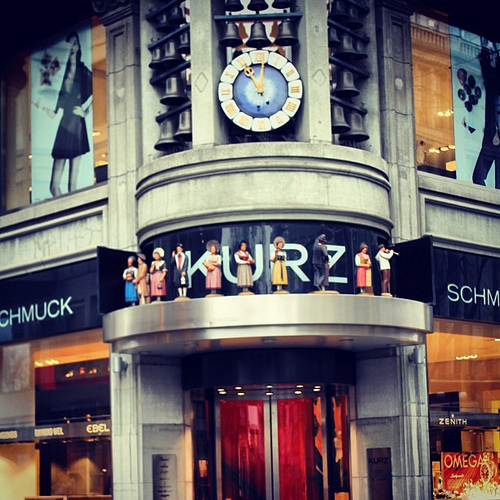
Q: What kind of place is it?
A: It is a store.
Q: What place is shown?
A: It is a store.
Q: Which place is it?
A: It is a store.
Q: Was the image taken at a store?
A: Yes, it was taken in a store.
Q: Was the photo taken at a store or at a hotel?
A: It was taken at a store.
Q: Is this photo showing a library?
A: No, the picture is showing a store.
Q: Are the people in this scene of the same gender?
A: Yes, all the people are female.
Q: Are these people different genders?
A: No, all the people are female.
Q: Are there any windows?
A: Yes, there is a window.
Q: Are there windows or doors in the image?
A: Yes, there is a window.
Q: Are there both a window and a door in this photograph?
A: Yes, there are both a window and a door.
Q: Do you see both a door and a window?
A: Yes, there are both a window and a door.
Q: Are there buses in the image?
A: No, there are no buses.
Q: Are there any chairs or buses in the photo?
A: No, there are no buses or chairs.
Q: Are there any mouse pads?
A: No, there are no mouse pads.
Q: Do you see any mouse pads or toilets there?
A: No, there are no mouse pads or toilets.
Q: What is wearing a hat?
A: The statue is wearing a hat.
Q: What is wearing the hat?
A: The statue is wearing a hat.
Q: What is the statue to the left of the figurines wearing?
A: The statue is wearing a hat.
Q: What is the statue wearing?
A: The statue is wearing a hat.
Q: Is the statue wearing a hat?
A: Yes, the statue is wearing a hat.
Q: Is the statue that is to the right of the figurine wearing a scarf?
A: No, the statue is wearing a hat.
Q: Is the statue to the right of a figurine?
A: Yes, the statue is to the right of a figurine.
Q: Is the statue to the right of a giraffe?
A: No, the statue is to the right of a figurine.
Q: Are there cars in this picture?
A: No, there are no cars.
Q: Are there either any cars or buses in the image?
A: No, there are no cars or buses.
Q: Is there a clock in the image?
A: Yes, there is a clock.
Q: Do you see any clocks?
A: Yes, there is a clock.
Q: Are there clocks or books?
A: Yes, there is a clock.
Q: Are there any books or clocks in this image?
A: Yes, there is a clock.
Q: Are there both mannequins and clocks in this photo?
A: No, there is a clock but no mannequins.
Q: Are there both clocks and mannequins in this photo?
A: No, there is a clock but no mannequins.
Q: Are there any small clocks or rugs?
A: Yes, there is a small clock.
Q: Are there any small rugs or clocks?
A: Yes, there is a small clock.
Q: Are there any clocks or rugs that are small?
A: Yes, the clock is small.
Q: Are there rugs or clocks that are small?
A: Yes, the clock is small.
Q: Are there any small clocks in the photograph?
A: Yes, there is a small clock.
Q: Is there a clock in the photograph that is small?
A: Yes, there is a clock that is small.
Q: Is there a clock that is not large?
A: Yes, there is a small clock.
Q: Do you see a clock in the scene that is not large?
A: Yes, there is a small clock.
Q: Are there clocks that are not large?
A: Yes, there is a small clock.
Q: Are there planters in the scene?
A: No, there are no planters.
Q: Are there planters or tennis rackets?
A: No, there are no planters or tennis rackets.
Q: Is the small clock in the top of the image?
A: Yes, the clock is in the top of the image.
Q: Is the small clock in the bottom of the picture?
A: No, the clock is in the top of the image.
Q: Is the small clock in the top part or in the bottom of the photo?
A: The clock is in the top of the image.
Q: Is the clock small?
A: Yes, the clock is small.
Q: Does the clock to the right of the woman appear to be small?
A: Yes, the clock is small.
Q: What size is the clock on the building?
A: The clock is small.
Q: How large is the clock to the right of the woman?
A: The clock is small.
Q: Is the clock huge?
A: No, the clock is small.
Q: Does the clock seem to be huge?
A: No, the clock is small.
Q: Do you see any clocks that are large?
A: No, there is a clock but it is small.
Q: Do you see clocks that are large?
A: No, there is a clock but it is small.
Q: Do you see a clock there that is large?
A: No, there is a clock but it is small.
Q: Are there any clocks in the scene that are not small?
A: No, there is a clock but it is small.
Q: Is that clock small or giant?
A: The clock is small.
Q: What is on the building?
A: The clock is on the building.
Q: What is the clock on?
A: The clock is on the building.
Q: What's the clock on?
A: The clock is on the building.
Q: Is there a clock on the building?
A: Yes, there is a clock on the building.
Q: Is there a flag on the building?
A: No, there is a clock on the building.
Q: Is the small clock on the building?
A: Yes, the clock is on the building.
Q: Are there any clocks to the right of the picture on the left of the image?
A: Yes, there is a clock to the right of the picture.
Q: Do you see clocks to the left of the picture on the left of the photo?
A: No, the clock is to the right of the picture.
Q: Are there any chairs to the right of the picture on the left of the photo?
A: No, there is a clock to the right of the picture.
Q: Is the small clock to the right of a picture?
A: Yes, the clock is to the right of a picture.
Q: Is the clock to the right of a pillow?
A: No, the clock is to the right of a picture.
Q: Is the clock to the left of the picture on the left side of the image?
A: No, the clock is to the right of the picture.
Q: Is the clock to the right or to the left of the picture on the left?
A: The clock is to the right of the picture.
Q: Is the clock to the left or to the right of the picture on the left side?
A: The clock is to the right of the picture.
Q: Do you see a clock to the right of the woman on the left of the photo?
A: Yes, there is a clock to the right of the woman.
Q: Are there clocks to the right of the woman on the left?
A: Yes, there is a clock to the right of the woman.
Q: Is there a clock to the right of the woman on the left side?
A: Yes, there is a clock to the right of the woman.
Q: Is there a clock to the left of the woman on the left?
A: No, the clock is to the right of the woman.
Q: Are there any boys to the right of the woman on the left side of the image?
A: No, there is a clock to the right of the woman.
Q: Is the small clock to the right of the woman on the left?
A: Yes, the clock is to the right of the woman.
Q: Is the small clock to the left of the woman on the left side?
A: No, the clock is to the right of the woman.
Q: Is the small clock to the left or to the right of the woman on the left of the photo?
A: The clock is to the right of the woman.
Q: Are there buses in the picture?
A: No, there are no buses.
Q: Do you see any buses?
A: No, there are no buses.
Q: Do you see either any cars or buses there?
A: No, there are no buses or cars.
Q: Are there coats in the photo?
A: Yes, there is a coat.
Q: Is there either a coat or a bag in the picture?
A: Yes, there is a coat.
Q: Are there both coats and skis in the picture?
A: No, there is a coat but no skis.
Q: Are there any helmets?
A: No, there are no helmets.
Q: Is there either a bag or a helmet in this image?
A: No, there are no helmets or bags.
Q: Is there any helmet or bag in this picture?
A: No, there are no helmets or bags.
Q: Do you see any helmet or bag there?
A: No, there are no helmets or bags.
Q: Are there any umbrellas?
A: No, there are no umbrellas.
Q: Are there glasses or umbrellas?
A: No, there are no umbrellas or glasses.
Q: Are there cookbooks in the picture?
A: No, there are no cookbooks.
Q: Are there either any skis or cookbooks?
A: No, there are no cookbooks or skis.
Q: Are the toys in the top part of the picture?
A: Yes, the toys are in the top of the image.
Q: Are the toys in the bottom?
A: No, the toys are in the top of the image.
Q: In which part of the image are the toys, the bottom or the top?
A: The toys are in the top of the image.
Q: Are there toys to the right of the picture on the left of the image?
A: Yes, there are toys to the right of the picture.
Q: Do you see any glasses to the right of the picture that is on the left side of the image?
A: No, there are toys to the right of the picture.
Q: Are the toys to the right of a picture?
A: Yes, the toys are to the right of a picture.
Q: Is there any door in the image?
A: Yes, there is a door.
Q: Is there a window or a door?
A: Yes, there is a door.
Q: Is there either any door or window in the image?
A: Yes, there is a door.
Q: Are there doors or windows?
A: Yes, there is a door.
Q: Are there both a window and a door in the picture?
A: Yes, there are both a door and a window.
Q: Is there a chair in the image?
A: No, there are no chairs.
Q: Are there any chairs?
A: No, there are no chairs.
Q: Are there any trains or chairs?
A: No, there are no chairs or trains.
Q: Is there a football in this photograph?
A: No, there are no footballs.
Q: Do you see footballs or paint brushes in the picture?
A: No, there are no footballs or paint brushes.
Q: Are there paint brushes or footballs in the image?
A: No, there are no footballs or paint brushes.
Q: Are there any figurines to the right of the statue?
A: Yes, there are figurines to the right of the statue.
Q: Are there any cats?
A: No, there are no cats.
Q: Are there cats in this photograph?
A: No, there are no cats.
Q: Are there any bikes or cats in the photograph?
A: No, there are no cats or bikes.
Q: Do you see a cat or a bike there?
A: No, there are no cats or bikes.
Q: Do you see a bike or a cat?
A: No, there are no cats or bikes.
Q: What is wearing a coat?
A: The figurine is wearing a coat.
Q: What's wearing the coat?
A: The figurine is wearing a coat.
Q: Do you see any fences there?
A: No, there are no fences.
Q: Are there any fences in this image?
A: No, there are no fences.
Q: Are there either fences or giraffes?
A: No, there are no fences or giraffes.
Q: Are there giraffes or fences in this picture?
A: No, there are no fences or giraffes.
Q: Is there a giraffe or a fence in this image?
A: No, there are no fences or giraffes.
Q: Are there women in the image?
A: Yes, there is a woman.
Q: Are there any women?
A: Yes, there is a woman.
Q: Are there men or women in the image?
A: Yes, there is a woman.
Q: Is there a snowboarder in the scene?
A: No, there are no snowboarders.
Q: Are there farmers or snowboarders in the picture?
A: No, there are no snowboarders or farmers.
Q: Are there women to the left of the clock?
A: Yes, there is a woman to the left of the clock.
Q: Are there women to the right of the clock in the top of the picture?
A: No, the woman is to the left of the clock.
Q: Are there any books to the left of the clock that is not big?
A: No, there is a woman to the left of the clock.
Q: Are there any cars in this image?
A: No, there are no cars.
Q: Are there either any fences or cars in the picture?
A: No, there are no cars or fences.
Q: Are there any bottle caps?
A: No, there are no bottle caps.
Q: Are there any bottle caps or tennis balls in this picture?
A: No, there are no bottle caps or tennis balls.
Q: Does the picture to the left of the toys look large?
A: Yes, the picture is large.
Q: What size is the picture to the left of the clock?
A: The picture is large.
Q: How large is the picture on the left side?
A: The picture is large.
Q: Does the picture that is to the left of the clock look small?
A: No, the picture is large.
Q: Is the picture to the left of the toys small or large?
A: The picture is large.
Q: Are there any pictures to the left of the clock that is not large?
A: Yes, there is a picture to the left of the clock.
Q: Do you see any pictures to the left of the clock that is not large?
A: Yes, there is a picture to the left of the clock.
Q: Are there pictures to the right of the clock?
A: No, the picture is to the left of the clock.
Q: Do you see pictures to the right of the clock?
A: No, the picture is to the left of the clock.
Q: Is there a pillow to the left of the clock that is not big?
A: No, there is a picture to the left of the clock.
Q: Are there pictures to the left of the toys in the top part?
A: Yes, there is a picture to the left of the toys.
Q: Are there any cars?
A: No, there are no cars.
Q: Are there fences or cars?
A: No, there are no cars or fences.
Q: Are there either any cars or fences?
A: No, there are no cars or fences.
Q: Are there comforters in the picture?
A: No, there are no comforters.